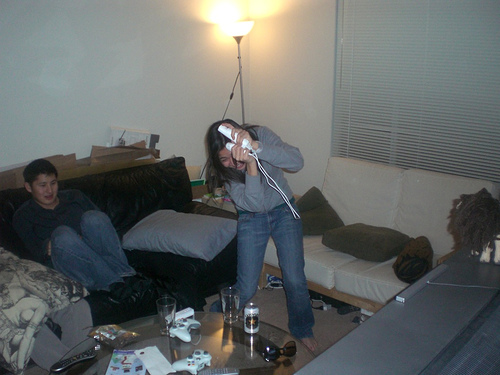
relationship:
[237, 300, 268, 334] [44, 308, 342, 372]
canned beverage on coffee table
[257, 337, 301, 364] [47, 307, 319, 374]
sunglasses on table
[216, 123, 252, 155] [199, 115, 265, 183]
remote over head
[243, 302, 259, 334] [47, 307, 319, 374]
can on table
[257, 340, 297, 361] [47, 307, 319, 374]
sunglasses on table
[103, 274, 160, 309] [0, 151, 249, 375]
feet on couch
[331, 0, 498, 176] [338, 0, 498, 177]
blinds over window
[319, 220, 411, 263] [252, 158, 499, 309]
pillow on couch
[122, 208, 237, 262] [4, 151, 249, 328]
grey pillow on couch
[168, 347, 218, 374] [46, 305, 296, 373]
controller on table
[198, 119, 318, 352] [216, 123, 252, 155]
girl playing remote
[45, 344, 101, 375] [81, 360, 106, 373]
remote on table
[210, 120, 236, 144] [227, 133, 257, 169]
remote in hands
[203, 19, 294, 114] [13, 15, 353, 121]
lamp leaning against wall